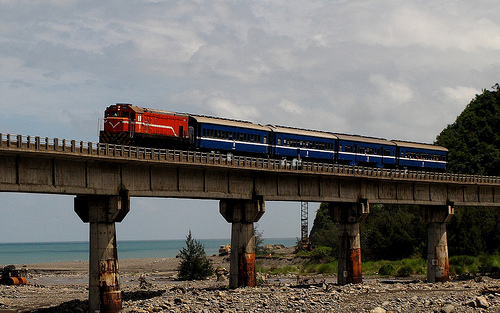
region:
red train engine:
[101, 97, 197, 140]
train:
[103, 102, 474, 199]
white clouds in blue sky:
[7, 15, 43, 40]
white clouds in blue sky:
[3, 53, 64, 95]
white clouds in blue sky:
[93, 32, 158, 79]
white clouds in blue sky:
[370, 40, 413, 96]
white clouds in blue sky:
[332, 29, 379, 70]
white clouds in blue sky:
[320, 75, 356, 125]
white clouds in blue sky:
[233, 13, 280, 58]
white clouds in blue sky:
[226, 39, 294, 96]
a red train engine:
[100, 100, 190, 151]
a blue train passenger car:
[185, 113, 269, 158]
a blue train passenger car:
[266, 122, 336, 164]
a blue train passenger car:
[334, 127, 395, 170]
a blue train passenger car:
[393, 134, 450, 170]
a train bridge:
[0, 130, 498, 303]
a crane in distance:
[300, 201, 310, 248]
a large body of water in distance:
[1, 239, 303, 264]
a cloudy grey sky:
[0, 3, 497, 241]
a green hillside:
[304, 88, 498, 254]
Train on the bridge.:
[92, 96, 454, 174]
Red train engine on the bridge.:
[96, 95, 196, 151]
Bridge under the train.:
[0, 133, 499, 311]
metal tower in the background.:
[295, 201, 312, 246]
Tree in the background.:
[171, 228, 215, 284]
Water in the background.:
[0, 236, 310, 270]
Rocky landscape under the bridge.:
[3, 272, 498, 312]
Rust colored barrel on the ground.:
[7, 273, 30, 285]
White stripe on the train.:
[192, 130, 449, 170]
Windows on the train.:
[196, 122, 265, 149]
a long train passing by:
[94, 90, 460, 181]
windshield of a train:
[102, 101, 134, 120]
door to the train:
[129, 110, 143, 132]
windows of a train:
[200, 121, 267, 144]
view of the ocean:
[2, 224, 299, 261]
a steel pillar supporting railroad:
[224, 215, 264, 286]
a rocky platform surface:
[272, 272, 495, 311]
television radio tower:
[290, 201, 318, 246]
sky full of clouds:
[324, 35, 471, 103]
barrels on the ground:
[3, 262, 32, 284]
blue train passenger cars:
[185, 113, 449, 172]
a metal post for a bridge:
[74, 193, 131, 305]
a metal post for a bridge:
[218, 198, 265, 288]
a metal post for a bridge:
[328, 204, 370, 288]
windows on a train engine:
[105, 108, 128, 117]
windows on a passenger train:
[199, 125, 261, 145]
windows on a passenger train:
[276, 133, 336, 153]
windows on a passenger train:
[340, 142, 396, 158]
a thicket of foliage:
[309, 87, 499, 251]